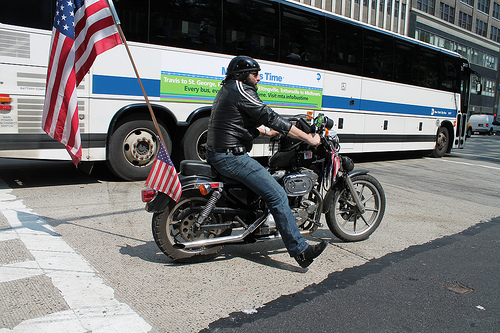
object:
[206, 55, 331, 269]
man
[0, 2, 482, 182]
bus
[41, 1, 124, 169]
flag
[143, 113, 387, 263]
bike